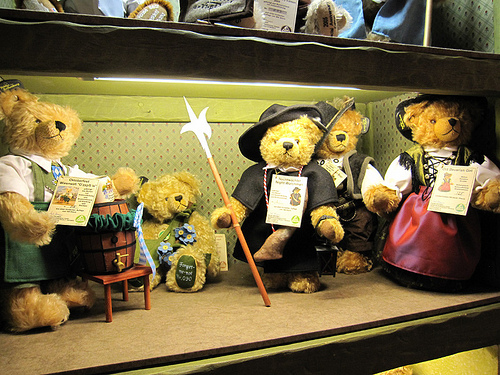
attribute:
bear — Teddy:
[218, 105, 350, 297]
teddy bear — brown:
[218, 102, 343, 294]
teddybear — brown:
[305, 95, 408, 283]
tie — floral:
[155, 217, 223, 277]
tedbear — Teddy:
[1, 87, 118, 331]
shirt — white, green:
[3, 155, 67, 204]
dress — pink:
[374, 146, 479, 283]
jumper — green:
[0, 156, 80, 286]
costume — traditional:
[399, 150, 440, 223]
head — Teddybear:
[253, 115, 322, 165]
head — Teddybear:
[136, 168, 198, 223]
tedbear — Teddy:
[209, 102, 344, 292]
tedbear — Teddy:
[135, 170, 218, 294]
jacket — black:
[231, 165, 351, 263]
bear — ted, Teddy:
[130, 169, 221, 295]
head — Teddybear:
[390, 97, 475, 153]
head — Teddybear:
[244, 103, 321, 178]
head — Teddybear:
[306, 107, 363, 146]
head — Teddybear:
[139, 165, 218, 220]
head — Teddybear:
[2, 83, 104, 165]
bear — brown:
[0, 85, 139, 332]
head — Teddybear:
[241, 110, 351, 250]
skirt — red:
[382, 179, 483, 301]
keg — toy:
[91, 199, 139, 275]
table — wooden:
[2, 261, 497, 372]